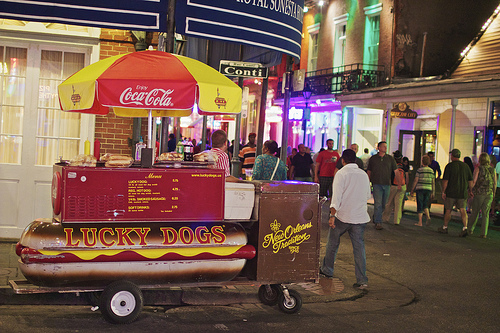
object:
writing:
[57, 223, 232, 249]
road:
[413, 267, 454, 311]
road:
[308, 299, 393, 328]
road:
[152, 315, 295, 332]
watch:
[326, 212, 337, 217]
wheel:
[274, 288, 303, 317]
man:
[311, 147, 379, 291]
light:
[272, 77, 391, 176]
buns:
[103, 152, 136, 167]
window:
[0, 44, 24, 162]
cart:
[10, 42, 328, 317]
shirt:
[439, 159, 477, 201]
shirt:
[328, 161, 375, 226]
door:
[0, 34, 101, 246]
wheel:
[101, 285, 147, 325]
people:
[461, 150, 496, 240]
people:
[438, 147, 475, 237]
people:
[410, 154, 435, 226]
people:
[421, 150, 444, 183]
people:
[381, 163, 410, 226]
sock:
[461, 225, 467, 229]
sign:
[218, 58, 268, 79]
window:
[360, 10, 385, 80]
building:
[300, 1, 466, 82]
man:
[364, 140, 402, 231]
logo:
[116, 82, 179, 113]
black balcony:
[301, 62, 391, 95]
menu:
[64, 169, 226, 225]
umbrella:
[52, 44, 243, 122]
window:
[31, 49, 86, 165]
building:
[0, 0, 303, 245]